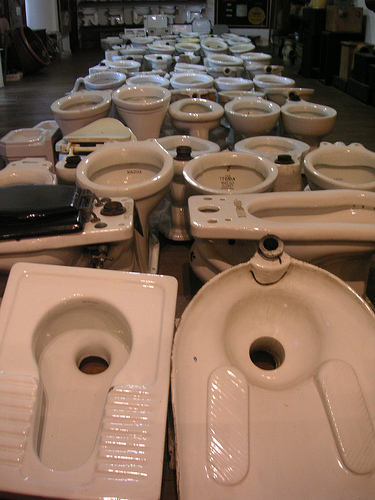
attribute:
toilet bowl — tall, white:
[112, 84, 172, 139]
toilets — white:
[7, 117, 358, 259]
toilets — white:
[4, 253, 358, 498]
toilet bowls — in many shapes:
[67, 29, 329, 138]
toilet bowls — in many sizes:
[1, 0, 356, 485]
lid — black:
[1, 181, 93, 236]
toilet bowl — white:
[222, 96, 281, 134]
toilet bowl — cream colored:
[168, 95, 226, 134]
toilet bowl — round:
[49, 90, 110, 130]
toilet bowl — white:
[3, 259, 178, 498]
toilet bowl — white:
[151, 134, 224, 242]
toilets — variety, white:
[65, 29, 300, 98]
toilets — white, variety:
[91, 2, 294, 92]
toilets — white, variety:
[35, 49, 317, 198]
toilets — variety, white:
[94, 36, 188, 91]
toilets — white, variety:
[199, 42, 295, 87]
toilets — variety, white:
[125, 42, 222, 95]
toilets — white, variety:
[82, 27, 206, 88]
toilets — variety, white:
[74, 4, 207, 28]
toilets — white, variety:
[93, 34, 282, 97]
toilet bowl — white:
[216, 72, 253, 93]